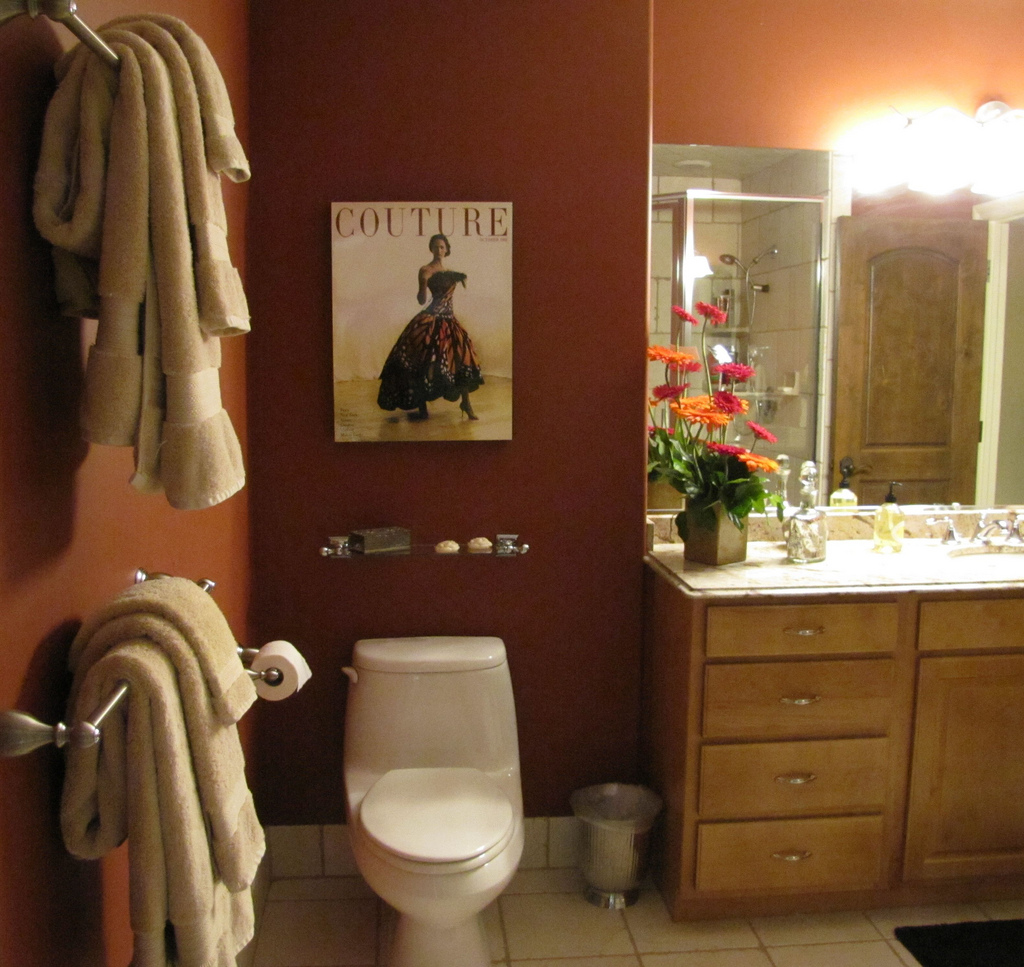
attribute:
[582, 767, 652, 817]
bag — garbage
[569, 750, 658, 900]
can — garbage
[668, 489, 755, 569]
vase — metal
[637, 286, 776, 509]
flowers — red, orange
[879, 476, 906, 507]
nozzle — black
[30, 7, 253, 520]
towel — cream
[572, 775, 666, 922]
can — garbage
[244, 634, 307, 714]
paper — toilet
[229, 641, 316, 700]
dispenser — toilet paper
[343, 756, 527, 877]
toilet seat — white, closed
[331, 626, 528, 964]
toilet — white, porcelain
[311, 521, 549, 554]
toiletries — miscellaneous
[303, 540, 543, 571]
shelf — clear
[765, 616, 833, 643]
handle — silver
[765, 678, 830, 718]
handle — silver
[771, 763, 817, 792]
handle — silver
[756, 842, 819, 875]
handle — silver